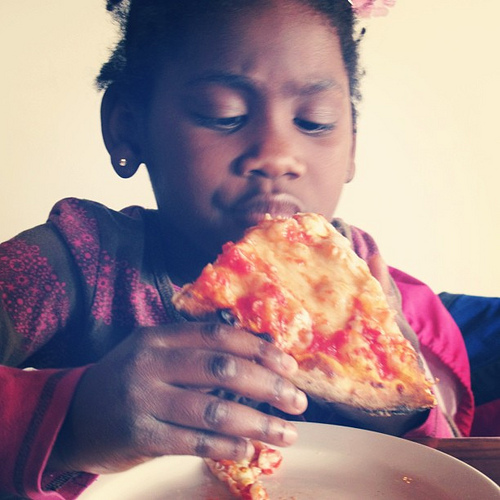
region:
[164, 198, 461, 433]
large slice of cheese pizza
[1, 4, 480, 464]
young black child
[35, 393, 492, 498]
nearly clean white plate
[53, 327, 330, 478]
hand holding the piece of pizza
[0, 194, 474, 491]
mostly pink sweater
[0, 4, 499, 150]
large white wall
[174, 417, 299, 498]
smaller chunk of cheese pizza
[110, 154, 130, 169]
small child's earning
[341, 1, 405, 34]
light pink flower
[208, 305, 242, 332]
slightly burnt portion of the pizza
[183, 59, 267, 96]
The left eyebrow of the little girl.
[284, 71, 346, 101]
The right eyebrow of the little girl.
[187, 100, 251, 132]
The left eye of the girl.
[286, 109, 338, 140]
The right eye of the girl.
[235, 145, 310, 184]
The nose of the girl.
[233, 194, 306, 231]
The lips of the girl.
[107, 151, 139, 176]
The earring in the girl's ear.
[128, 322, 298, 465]
The girl's four fingers.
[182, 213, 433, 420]
The slice of pizza in the girl's hand.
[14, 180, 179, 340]
The star design on the girl's shirt.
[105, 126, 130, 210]
girl wears earring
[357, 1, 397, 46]
girl wears pink bow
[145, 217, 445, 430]
girl is eating pizza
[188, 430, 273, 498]
pizza on plate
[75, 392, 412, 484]
plate is white and ceramic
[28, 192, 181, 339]
girl wears pink hoodie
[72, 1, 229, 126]
girl has curly hair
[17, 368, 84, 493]
dark sewing stripe on hoodie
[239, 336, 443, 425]
pizza has burnt crust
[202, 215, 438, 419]
pizza with cheese and sauce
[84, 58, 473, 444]
girl holding a piece of pizza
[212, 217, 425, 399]
slice of cheese and tomato pizza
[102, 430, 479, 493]
white plate with pizza on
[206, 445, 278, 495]
small piece of cheese and tomato pizza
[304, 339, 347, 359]
tomato pizza sauce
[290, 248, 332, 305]
bubbled cheese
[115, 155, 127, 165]
diamond earring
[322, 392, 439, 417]
burnt crust of pizza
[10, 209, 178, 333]
red and brown floral top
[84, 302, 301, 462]
hand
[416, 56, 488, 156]
The wall is yellow.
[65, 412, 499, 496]
The plate is white.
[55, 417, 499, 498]
The plate is round.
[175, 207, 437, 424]
A slice of pizza.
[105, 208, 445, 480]
The pizza is being held.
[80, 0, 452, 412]
The person is eating pizza.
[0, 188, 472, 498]
The person is wearing a pink and gray top.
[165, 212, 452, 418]
The pizza has no toppings on it.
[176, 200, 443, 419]
The pizza slice is large.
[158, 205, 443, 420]
The pizza has cheese on it.